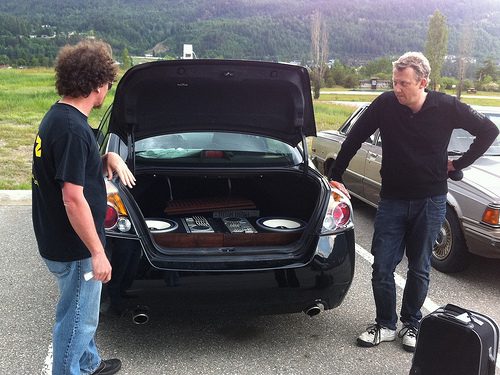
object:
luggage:
[407, 303, 500, 375]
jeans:
[40, 255, 103, 375]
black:
[108, 158, 330, 273]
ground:
[0, 151, 500, 375]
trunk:
[120, 146, 323, 271]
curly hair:
[52, 38, 116, 99]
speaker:
[142, 215, 310, 247]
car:
[309, 104, 499, 273]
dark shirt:
[326, 88, 499, 199]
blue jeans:
[370, 195, 447, 329]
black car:
[89, 58, 357, 323]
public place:
[0, 14, 499, 375]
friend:
[31, 39, 135, 375]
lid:
[110, 59, 317, 145]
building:
[351, 79, 396, 91]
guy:
[327, 49, 498, 352]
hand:
[327, 176, 351, 199]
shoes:
[352, 320, 418, 351]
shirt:
[30, 99, 109, 261]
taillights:
[315, 188, 354, 238]